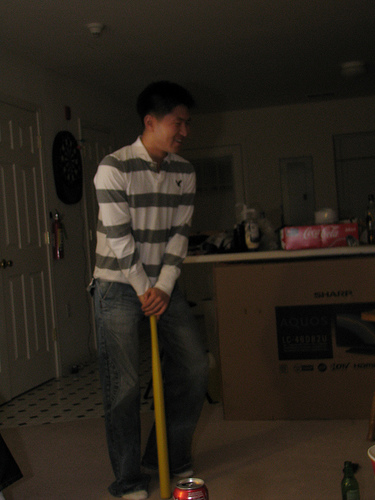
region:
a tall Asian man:
[76, 65, 248, 497]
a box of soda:
[271, 219, 367, 258]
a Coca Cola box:
[278, 209, 368, 252]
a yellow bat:
[141, 295, 187, 499]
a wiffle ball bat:
[138, 280, 188, 499]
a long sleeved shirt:
[94, 134, 208, 310]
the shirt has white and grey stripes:
[84, 134, 220, 318]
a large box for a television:
[208, 245, 370, 427]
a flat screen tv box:
[205, 258, 373, 424]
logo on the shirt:
[172, 175, 187, 192]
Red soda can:
[174, 475, 210, 498]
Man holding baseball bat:
[143, 291, 177, 496]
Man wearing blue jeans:
[86, 275, 206, 498]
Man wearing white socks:
[113, 464, 198, 496]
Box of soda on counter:
[279, 221, 363, 251]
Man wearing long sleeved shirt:
[88, 135, 197, 301]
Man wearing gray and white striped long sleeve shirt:
[92, 135, 201, 298]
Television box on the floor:
[209, 255, 372, 423]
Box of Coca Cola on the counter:
[275, 219, 361, 249]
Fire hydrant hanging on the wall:
[46, 205, 70, 261]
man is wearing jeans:
[75, 26, 229, 469]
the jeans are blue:
[70, 256, 243, 445]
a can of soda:
[160, 467, 215, 498]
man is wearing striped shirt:
[78, 140, 220, 328]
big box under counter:
[186, 255, 370, 418]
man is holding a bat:
[122, 249, 217, 487]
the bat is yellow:
[134, 264, 196, 495]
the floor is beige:
[171, 405, 320, 491]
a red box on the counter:
[257, 213, 366, 255]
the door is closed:
[5, 88, 52, 401]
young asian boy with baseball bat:
[89, 79, 211, 499]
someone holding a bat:
[140, 289, 172, 499]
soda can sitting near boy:
[170, 475, 212, 499]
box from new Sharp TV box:
[214, 254, 374, 423]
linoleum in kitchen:
[0, 352, 153, 426]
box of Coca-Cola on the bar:
[279, 221, 360, 249]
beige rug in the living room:
[1, 416, 372, 498]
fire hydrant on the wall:
[47, 209, 71, 262]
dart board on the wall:
[49, 128, 85, 206]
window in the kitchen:
[185, 142, 246, 235]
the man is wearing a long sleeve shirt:
[91, 138, 194, 292]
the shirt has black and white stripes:
[95, 137, 198, 297]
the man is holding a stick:
[148, 315, 172, 498]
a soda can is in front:
[174, 476, 209, 498]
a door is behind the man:
[4, 107, 64, 407]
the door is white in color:
[4, 105, 66, 403]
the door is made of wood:
[0, 106, 61, 409]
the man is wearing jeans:
[84, 276, 198, 498]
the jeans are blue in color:
[89, 279, 192, 496]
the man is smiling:
[171, 134, 180, 145]